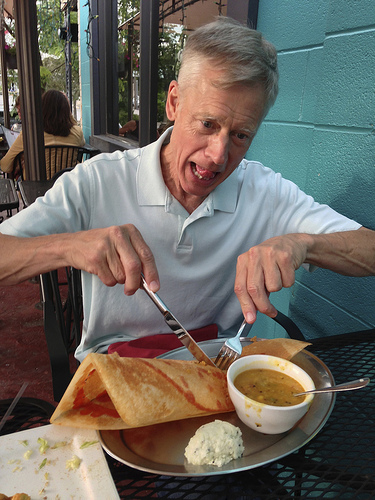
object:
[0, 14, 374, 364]
man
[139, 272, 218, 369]
knife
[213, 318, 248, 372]
fork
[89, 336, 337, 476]
platter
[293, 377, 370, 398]
spoon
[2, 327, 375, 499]
table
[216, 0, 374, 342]
wall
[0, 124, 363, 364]
shirt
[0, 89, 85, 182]
woman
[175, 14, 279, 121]
hair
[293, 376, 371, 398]
utensil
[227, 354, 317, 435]
bowl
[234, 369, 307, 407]
soup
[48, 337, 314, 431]
food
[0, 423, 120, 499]
plate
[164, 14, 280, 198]
head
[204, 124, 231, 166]
nose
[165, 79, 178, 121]
ear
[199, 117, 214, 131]
eye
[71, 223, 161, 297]
hand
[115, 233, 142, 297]
finger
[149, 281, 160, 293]
nail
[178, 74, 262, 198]
face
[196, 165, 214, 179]
tounge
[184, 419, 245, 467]
lump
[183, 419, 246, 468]
potato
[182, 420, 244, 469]
salad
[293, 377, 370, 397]
handle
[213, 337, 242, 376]
bottom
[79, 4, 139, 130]
lights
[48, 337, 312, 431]
tortilla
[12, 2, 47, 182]
pillar